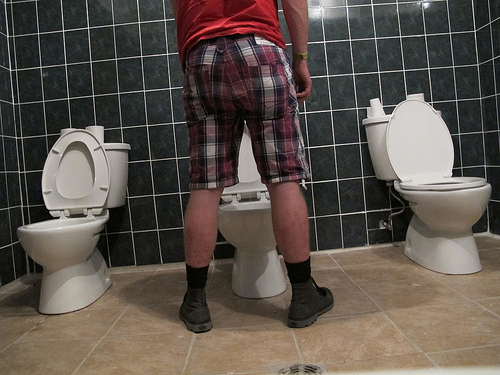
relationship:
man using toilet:
[160, 0, 340, 335] [358, 88, 495, 279]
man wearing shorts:
[160, 0, 340, 335] [181, 28, 311, 190]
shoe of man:
[285, 276, 337, 330] [160, 0, 340, 335]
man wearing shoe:
[160, 0, 340, 335] [285, 276, 337, 330]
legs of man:
[181, 186, 314, 261] [160, 0, 340, 335]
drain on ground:
[273, 360, 323, 374] [1, 232, 499, 368]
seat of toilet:
[39, 126, 109, 216] [19, 134, 135, 317]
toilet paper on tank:
[366, 96, 385, 118] [361, 104, 448, 184]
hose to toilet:
[381, 183, 410, 226] [358, 88, 495, 279]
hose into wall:
[382, 181, 406, 230] [13, 6, 496, 269]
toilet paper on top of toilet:
[59, 121, 106, 142] [19, 134, 135, 317]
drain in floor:
[273, 360, 323, 374] [4, 230, 498, 371]